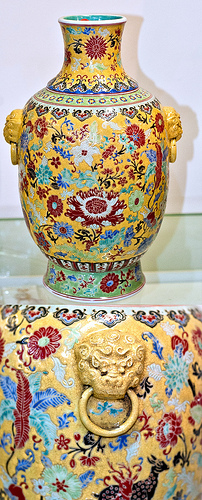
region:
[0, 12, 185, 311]
this is a vase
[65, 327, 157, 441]
yellow emblem on vase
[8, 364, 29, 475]
red feather design on vase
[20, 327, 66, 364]
red painted on flower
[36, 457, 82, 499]
light green flower painted on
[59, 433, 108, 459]
black vine painted on vase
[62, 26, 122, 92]
background of vase is yellow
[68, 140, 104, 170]
white flower painted on vase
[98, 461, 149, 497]
red dear on vase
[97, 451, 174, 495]
black animal on vase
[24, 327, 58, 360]
the flower is red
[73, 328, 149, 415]
a yellow intricate carving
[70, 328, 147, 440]
an animals head with a ring on a vase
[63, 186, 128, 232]
red and white flower on an antique vase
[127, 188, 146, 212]
green and red flower on an antique vase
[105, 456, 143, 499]
a red deer's head on a vase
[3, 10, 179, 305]
a tall decorated antique pottery vase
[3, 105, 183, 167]
a pair of yellow heads with rings on the sides of a vase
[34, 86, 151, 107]
pattern around the neck of a vase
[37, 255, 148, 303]
round base of a pottery vase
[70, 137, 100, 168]
white and red flower on a vase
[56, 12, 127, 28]
circular opening in the top of a vase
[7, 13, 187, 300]
a big vase sits on this surface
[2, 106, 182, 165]
the vase has two handles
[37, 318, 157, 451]
a closer look at the handle area of the vase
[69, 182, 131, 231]
a red and white flower is on the vase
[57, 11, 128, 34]
the opening of the vase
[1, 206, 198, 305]
the vase is sitting on a glass surface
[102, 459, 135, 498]
the buck displayed on the vase has a set of antlers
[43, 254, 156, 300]
the base of the vase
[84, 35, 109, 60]
a red sun is painted on the neck of the vase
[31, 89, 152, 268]
the vase has a very colorful pattern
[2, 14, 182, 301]
A large decorative vase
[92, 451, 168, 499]
Deer painted against a yellow background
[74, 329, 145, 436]
A ring that is afixed to the pot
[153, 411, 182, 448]
Flower on side of vase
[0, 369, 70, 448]
Large multicolored flower featured on vase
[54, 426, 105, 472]
Stalk of flower on side of vase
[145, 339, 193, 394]
Turqoise colored flower on vase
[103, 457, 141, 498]
Red steer standing next to fawn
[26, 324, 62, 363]
Big red flower on vase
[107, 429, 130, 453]
Blue colored plant on vase